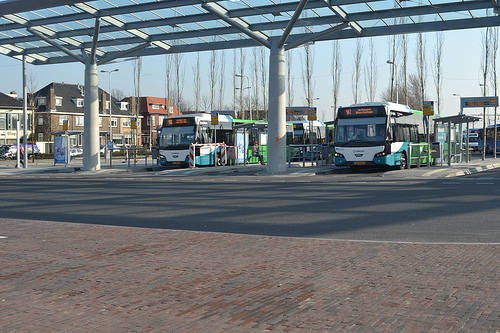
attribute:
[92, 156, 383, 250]
sidewalk — red, brick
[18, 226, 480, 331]
sidewalk — brick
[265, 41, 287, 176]
pylon — cement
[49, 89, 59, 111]
chimney — brick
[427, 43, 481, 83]
sky — blue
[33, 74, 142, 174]
house — brown, brick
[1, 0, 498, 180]
frame — long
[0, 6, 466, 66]
framework — metal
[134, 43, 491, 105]
trees — tall, thin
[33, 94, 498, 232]
busstop — metal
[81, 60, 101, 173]
pillar — thick, white, metal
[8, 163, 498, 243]
ground — smooth, open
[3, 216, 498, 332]
road — tarmac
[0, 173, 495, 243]
pavement — brick